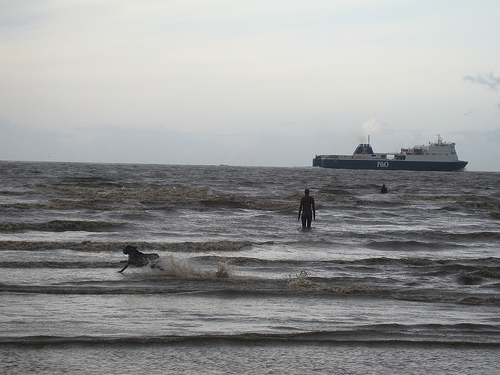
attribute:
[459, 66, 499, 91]
cloud — small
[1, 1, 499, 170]
sky — overcast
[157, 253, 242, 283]
waves — splashing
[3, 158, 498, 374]
water — large, dark, gray, wavy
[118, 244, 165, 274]
dog — running, black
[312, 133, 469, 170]
ship — large, blue, white, dark blue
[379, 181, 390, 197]
person — swimming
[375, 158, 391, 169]
text — white